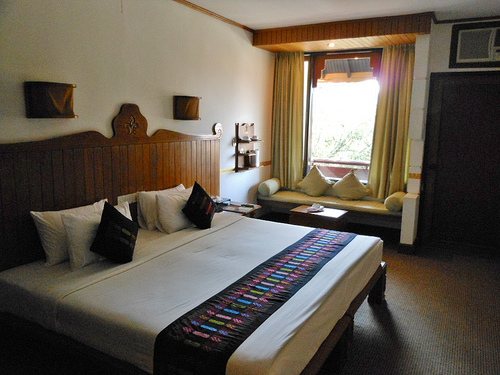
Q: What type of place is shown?
A: It is a hotel room.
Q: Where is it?
A: This is at the hotel room.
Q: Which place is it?
A: It is a hotel room.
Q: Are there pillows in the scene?
A: Yes, there is a pillow.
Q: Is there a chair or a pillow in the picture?
A: Yes, there is a pillow.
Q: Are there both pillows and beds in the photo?
A: Yes, there are both a pillow and a bed.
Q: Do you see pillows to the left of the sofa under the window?
A: Yes, there is a pillow to the left of the sofa.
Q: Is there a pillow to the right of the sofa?
A: No, the pillow is to the left of the sofa.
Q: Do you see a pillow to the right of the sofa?
A: No, the pillow is to the left of the sofa.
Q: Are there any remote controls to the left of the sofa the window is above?
A: No, there is a pillow to the left of the sofa.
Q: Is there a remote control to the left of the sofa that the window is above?
A: No, there is a pillow to the left of the sofa.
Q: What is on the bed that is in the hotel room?
A: The pillow is on the bed.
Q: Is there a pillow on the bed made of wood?
A: Yes, there is a pillow on the bed.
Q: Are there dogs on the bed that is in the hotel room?
A: No, there is a pillow on the bed.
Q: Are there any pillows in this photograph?
A: Yes, there is a pillow.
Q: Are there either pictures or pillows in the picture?
A: Yes, there is a pillow.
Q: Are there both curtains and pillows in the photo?
A: Yes, there are both a pillow and a curtain.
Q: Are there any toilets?
A: No, there are no toilets.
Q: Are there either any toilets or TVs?
A: No, there are no toilets or tvs.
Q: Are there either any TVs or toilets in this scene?
A: No, there are no toilets or tvs.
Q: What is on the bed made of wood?
A: The pillow is on the bed.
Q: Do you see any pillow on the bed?
A: Yes, there is a pillow on the bed.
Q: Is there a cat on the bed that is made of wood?
A: No, there is a pillow on the bed.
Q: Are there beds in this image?
A: Yes, there is a bed.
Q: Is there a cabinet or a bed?
A: Yes, there is a bed.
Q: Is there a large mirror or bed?
A: Yes, there is a large bed.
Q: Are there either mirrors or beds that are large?
A: Yes, the bed is large.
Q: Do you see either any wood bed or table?
A: Yes, there is a wood bed.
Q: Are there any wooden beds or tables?
A: Yes, there is a wood bed.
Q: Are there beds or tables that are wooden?
A: Yes, the bed is wooden.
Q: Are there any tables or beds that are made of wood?
A: Yes, the bed is made of wood.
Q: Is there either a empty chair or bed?
A: Yes, there is an empty bed.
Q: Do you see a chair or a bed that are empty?
A: Yes, the bed is empty.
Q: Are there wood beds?
A: Yes, there is a bed that is made of wood.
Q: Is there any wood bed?
A: Yes, there is a bed that is made of wood.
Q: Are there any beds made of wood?
A: Yes, there is a bed that is made of wood.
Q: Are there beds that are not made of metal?
A: Yes, there is a bed that is made of wood.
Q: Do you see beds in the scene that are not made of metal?
A: Yes, there is a bed that is made of wood.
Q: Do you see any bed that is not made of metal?
A: Yes, there is a bed that is made of wood.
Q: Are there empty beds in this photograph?
A: Yes, there is an empty bed.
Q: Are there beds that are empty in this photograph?
A: Yes, there is an empty bed.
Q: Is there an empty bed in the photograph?
A: Yes, there is an empty bed.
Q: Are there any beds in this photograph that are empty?
A: Yes, there is a bed that is empty.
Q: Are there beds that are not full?
A: Yes, there is a empty bed.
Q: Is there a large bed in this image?
A: Yes, there is a large bed.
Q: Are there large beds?
A: Yes, there is a large bed.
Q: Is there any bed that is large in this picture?
A: Yes, there is a large bed.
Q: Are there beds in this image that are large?
A: Yes, there is a bed that is large.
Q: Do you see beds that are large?
A: Yes, there is a bed that is large.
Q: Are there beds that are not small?
A: Yes, there is a large bed.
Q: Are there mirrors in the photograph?
A: No, there are no mirrors.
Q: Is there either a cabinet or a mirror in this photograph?
A: No, there are no mirrors or cabinets.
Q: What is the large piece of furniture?
A: The piece of furniture is a bed.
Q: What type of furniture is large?
A: The furniture is a bed.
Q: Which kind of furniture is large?
A: The furniture is a bed.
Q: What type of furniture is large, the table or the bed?
A: The bed is large.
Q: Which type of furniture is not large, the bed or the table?
A: The table is not large.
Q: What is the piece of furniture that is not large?
A: The piece of furniture is a table.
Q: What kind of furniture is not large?
A: The furniture is a table.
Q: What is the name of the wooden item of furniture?
A: The piece of furniture is a bed.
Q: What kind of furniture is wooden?
A: The furniture is a bed.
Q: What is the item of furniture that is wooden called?
A: The piece of furniture is a bed.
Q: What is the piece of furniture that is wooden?
A: The piece of furniture is a bed.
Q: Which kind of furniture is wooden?
A: The furniture is a bed.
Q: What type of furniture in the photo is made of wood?
A: The furniture is a bed.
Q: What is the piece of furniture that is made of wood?
A: The piece of furniture is a bed.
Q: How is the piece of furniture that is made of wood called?
A: The piece of furniture is a bed.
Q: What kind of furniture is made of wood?
A: The furniture is a bed.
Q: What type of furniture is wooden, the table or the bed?
A: The bed is wooden.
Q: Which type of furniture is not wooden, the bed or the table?
A: The table is not wooden.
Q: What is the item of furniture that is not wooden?
A: The piece of furniture is a table.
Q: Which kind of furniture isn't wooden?
A: The furniture is a table.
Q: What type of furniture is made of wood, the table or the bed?
A: The bed is made of wood.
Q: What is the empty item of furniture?
A: The piece of furniture is a bed.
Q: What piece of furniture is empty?
A: The piece of furniture is a bed.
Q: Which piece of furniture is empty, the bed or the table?
A: The bed is empty.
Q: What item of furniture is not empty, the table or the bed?
A: The table is not empty.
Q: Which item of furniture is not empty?
A: The piece of furniture is a table.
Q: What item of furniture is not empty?
A: The piece of furniture is a table.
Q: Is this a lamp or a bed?
A: This is a bed.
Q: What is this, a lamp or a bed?
A: This is a bed.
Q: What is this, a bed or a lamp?
A: This is a bed.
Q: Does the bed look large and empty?
A: Yes, the bed is large and empty.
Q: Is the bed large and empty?
A: Yes, the bed is large and empty.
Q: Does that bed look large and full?
A: No, the bed is large but empty.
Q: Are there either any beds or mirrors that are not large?
A: No, there is a bed but it is large.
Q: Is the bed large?
A: Yes, the bed is large.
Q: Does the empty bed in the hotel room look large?
A: Yes, the bed is large.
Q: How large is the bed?
A: The bed is large.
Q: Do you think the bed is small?
A: No, the bed is large.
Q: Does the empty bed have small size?
A: No, the bed is large.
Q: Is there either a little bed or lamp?
A: No, there is a bed but it is large.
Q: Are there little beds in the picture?
A: No, there is a bed but it is large.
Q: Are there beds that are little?
A: No, there is a bed but it is large.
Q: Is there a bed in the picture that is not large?
A: No, there is a bed but it is large.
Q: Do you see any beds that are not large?
A: No, there is a bed but it is large.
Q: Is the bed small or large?
A: The bed is large.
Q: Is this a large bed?
A: Yes, this is a large bed.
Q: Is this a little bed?
A: No, this is a large bed.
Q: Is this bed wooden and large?
A: Yes, the bed is wooden and large.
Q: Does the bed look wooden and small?
A: No, the bed is wooden but large.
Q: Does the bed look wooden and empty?
A: Yes, the bed is wooden and empty.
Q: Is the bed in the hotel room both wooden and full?
A: No, the bed is wooden but empty.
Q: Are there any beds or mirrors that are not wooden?
A: No, there is a bed but it is wooden.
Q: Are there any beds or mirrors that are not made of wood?
A: No, there is a bed but it is made of wood.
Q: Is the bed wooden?
A: Yes, the bed is wooden.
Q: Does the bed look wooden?
A: Yes, the bed is wooden.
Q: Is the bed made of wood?
A: Yes, the bed is made of wood.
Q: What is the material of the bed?
A: The bed is made of wood.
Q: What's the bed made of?
A: The bed is made of wood.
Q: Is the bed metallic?
A: No, the bed is wooden.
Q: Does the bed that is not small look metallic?
A: No, the bed is wooden.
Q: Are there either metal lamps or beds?
A: No, there is a bed but it is wooden.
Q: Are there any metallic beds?
A: No, there is a bed but it is wooden.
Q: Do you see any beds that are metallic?
A: No, there is a bed but it is wooden.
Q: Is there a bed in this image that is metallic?
A: No, there is a bed but it is wooden.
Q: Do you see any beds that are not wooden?
A: No, there is a bed but it is wooden.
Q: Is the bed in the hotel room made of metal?
A: No, the bed is made of wood.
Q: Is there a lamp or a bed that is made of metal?
A: No, there is a bed but it is made of wood.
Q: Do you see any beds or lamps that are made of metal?
A: No, there is a bed but it is made of wood.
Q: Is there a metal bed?
A: No, there is a bed but it is made of wood.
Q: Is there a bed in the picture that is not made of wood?
A: No, there is a bed but it is made of wood.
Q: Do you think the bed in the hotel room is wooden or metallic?
A: The bed is wooden.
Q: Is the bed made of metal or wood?
A: The bed is made of wood.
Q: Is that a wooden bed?
A: Yes, that is a wooden bed.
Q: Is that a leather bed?
A: No, that is a wooden bed.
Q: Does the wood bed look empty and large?
A: Yes, the bed is empty and large.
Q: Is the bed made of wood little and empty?
A: No, the bed is empty but large.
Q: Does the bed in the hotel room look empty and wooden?
A: Yes, the bed is empty and wooden.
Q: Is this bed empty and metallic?
A: No, the bed is empty but wooden.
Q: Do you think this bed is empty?
A: Yes, the bed is empty.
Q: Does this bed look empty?
A: Yes, the bed is empty.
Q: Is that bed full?
A: No, the bed is empty.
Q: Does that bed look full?
A: No, the bed is empty.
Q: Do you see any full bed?
A: No, there is a bed but it is empty.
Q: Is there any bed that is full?
A: No, there is a bed but it is empty.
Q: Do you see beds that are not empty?
A: No, there is a bed but it is empty.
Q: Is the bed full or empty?
A: The bed is empty.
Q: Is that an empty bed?
A: Yes, that is an empty bed.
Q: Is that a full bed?
A: No, that is an empty bed.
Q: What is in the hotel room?
A: The bed is in the hotel room.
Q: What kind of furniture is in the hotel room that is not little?
A: The piece of furniture is a bed.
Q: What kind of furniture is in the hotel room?
A: The piece of furniture is a bed.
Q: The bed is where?
A: The bed is in the hotel room.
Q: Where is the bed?
A: The bed is in the hotel room.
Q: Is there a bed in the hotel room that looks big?
A: Yes, there is a bed in the hotel room.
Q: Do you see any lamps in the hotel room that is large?
A: No, there is a bed in the hotel room.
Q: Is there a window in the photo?
A: Yes, there is a window.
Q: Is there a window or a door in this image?
A: Yes, there is a window.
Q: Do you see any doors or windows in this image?
A: Yes, there is a window.